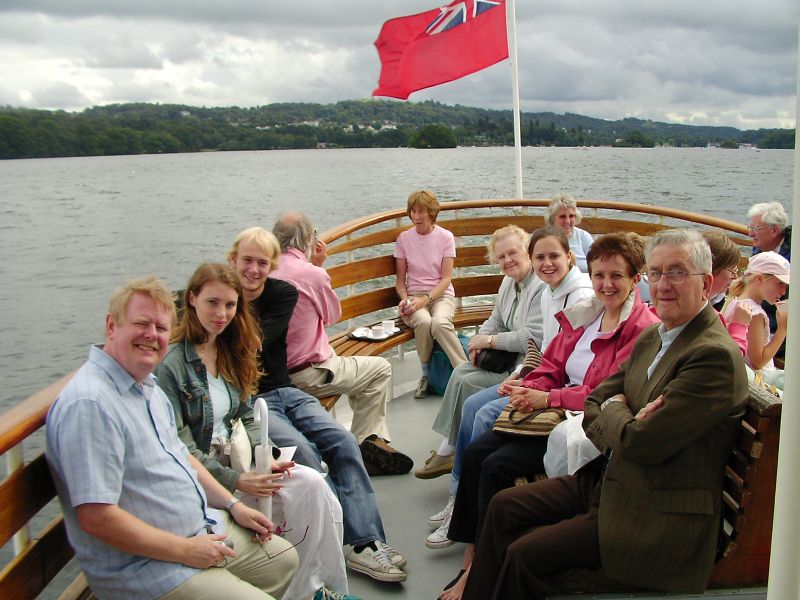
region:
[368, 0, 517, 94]
flag known as the British Red Ensign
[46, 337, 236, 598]
man wearing a light blue button down shirt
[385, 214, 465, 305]
lady wears a pink short sleeved t-shirt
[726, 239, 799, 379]
young girl in pink sips on a drink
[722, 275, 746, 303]
a blond pony tail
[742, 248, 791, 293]
a light pink cap with visor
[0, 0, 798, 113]
a dark and cloudy sky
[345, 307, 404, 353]
a tray with white cups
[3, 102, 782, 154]
ridge on the far shore with trees and buildings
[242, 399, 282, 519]
a white umbrella with white handle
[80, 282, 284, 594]
a person is sitting down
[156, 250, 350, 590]
a person is sitting down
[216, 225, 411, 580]
a person is sitting down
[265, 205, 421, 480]
a person is sitting down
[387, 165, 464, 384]
a person is sitting down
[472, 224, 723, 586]
a person is sitting down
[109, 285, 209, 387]
the head of a man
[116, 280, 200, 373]
the face of a man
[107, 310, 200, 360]
the eyes of a man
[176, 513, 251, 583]
the hand of a man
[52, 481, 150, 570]
the elbow of a man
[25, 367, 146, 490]
the shoulder of a man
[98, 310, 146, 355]
the ear of a man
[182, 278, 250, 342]
the head of a woman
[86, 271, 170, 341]
the hair of a man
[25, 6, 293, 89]
grey and white sky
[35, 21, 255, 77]
thick clouds in sky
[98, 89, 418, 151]
green trees in distance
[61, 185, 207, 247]
small waves on water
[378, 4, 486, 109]
red and blue flag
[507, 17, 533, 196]
flag on white pole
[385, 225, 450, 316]
woman has pink shirt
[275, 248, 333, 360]
man has pink shirt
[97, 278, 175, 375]
Head of a man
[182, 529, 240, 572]
Hand of a man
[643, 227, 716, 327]
Head of a man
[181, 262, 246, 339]
Head of a woman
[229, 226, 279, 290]
Head of a man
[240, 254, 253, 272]
Left eye of a man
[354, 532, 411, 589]
Shoes on a man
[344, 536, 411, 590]
White shoes on a man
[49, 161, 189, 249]
Large body of water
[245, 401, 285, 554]
the umbrella is white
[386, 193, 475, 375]
woman wearing pink shirt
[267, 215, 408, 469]
man wearing pink shirt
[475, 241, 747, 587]
man wearing sport coat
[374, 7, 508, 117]
red blue and white flag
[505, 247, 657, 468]
woman wearing pink coat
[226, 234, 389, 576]
man wearing black shirt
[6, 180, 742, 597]
boat the people are sitting on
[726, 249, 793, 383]
girl wearing pink cap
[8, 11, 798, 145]
cloud covered gray sky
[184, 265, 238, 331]
person has a head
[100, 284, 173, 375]
person has a head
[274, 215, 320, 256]
person has a head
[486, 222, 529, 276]
person has a head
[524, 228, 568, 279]
person has a head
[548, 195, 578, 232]
person has a head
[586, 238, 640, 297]
person has a head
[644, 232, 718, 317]
person has a head